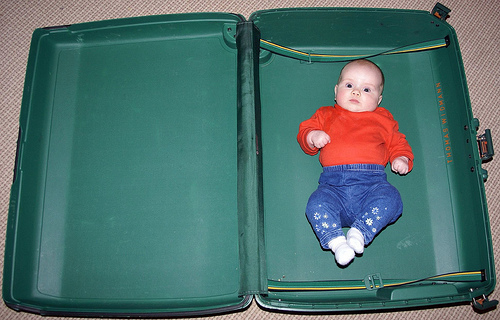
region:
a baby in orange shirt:
[305, 52, 411, 273]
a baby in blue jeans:
[280, 48, 417, 311]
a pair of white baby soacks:
[306, 217, 369, 274]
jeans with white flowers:
[273, 184, 420, 273]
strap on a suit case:
[258, 28, 433, 73]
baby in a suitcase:
[0, 16, 485, 301]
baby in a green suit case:
[61, 25, 463, 318]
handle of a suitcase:
[466, 102, 499, 195]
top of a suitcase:
[0, 2, 243, 318]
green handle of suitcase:
[461, 90, 498, 188]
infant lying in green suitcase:
[38, 27, 489, 283]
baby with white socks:
[321, 226, 380, 266]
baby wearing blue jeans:
[298, 166, 415, 236]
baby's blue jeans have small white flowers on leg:
[306, 207, 379, 239]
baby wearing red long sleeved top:
[298, 105, 418, 182]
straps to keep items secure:
[251, 31, 451, 67]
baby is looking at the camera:
[322, 60, 388, 108]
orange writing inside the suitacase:
[425, 69, 465, 188]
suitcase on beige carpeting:
[8, 8, 145, 52]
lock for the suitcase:
[457, 102, 496, 187]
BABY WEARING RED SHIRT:
[295, 57, 415, 267]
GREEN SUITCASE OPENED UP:
[2, 7, 497, 316]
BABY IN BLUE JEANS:
[295, 54, 415, 268]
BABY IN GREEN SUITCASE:
[288, 54, 417, 269]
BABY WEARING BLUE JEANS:
[293, 54, 417, 268]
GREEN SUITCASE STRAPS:
[265, 270, 484, 295]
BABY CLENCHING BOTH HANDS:
[295, 55, 417, 271]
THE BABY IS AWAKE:
[295, 55, 419, 269]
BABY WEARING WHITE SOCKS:
[297, 55, 414, 270]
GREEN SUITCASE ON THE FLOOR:
[7, 0, 497, 317]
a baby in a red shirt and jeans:
[291, 57, 417, 267]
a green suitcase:
[2, 2, 497, 318]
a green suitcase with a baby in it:
[0, 0, 497, 318]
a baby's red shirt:
[294, 103, 416, 175]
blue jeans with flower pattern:
[300, 159, 407, 267]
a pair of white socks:
[327, 221, 371, 269]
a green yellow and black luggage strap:
[257, 265, 487, 293]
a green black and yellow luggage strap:
[255, 35, 455, 63]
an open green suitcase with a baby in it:
[3, 7, 498, 319]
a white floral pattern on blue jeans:
[303, 201, 389, 240]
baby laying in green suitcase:
[298, 41, 418, 279]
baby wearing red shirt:
[317, 42, 412, 174]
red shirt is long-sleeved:
[285, 102, 420, 174]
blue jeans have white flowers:
[294, 181, 406, 243]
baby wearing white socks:
[278, 207, 393, 258]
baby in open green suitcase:
[28, 22, 489, 310]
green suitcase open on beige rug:
[20, 18, 498, 308]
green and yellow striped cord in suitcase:
[230, 22, 491, 54]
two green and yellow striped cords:
[265, 2, 476, 313]